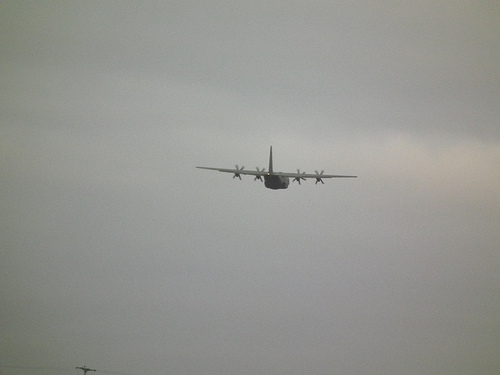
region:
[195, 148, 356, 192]
A plane in the sky.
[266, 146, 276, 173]
The tail of the plane.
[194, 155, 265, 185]
The wing of the plane.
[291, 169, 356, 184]
The right wing of the plane.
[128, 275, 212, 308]
Part of the grey sky.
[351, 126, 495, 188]
A white cloud in the sky.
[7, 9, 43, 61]
A dark part of the sky.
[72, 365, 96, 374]
A dark object in the sky.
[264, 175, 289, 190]
The body of the plane.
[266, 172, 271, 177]
A white spot on the plane.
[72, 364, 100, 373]
Plane flying in cloudy weather.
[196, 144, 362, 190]
Plane flying high in the sky.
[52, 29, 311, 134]
Heavy clouds in sky.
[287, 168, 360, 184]
Right wing on plane.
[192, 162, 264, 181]
Left wing on plane.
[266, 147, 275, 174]
Tail of airplane.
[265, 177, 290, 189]
Airplane body flying in mid-air.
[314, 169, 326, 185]
Engine on plane wing.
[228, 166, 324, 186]
Four engines on plane wings.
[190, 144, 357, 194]
Gray plane flying in gray skies.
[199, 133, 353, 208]
C130 Hercules aircraft in sky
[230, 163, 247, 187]
Propeller engine on wing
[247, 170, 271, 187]
Propeller engine on wing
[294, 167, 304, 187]
Propeller engine on wing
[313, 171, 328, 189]
Propeller engine on wing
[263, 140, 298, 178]
Raised tail on rear of plane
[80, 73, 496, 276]
Gray overcast skies ahead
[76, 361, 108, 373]
Top of electrical pole on ground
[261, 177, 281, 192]
rear cargo door of plane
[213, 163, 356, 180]
Large wingspan for supporting loads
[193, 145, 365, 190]
a plane in the clouds taking off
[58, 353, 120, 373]
telephone pole just below plane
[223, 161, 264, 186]
engines that keep the plane flying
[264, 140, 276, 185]
tail of plane that gives the plane direction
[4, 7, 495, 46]
cloudy sky that affects the planes vision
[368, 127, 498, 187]
white cloud that is blocking the sun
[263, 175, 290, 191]
body of plane that holds passengers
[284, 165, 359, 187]
right wing of plane used to glide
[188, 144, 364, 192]
airplane with no landing gear showing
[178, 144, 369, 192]
plane circling airport waiting to land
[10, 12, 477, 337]
the sky is overcast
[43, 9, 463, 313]
the clouds are thick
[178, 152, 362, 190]
the wing span is long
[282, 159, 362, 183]
the tip of the wing is pointy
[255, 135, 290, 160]
the tip of the tail is sharp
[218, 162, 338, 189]
four propellers on the plane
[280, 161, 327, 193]
the propellers are not moving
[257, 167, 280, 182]
a light on the back of the plane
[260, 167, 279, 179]
the light is small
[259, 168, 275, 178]
the light is white